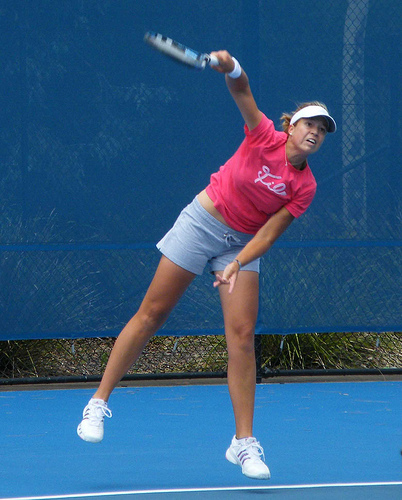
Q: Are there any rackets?
A: Yes, there is a racket.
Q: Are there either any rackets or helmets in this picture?
A: Yes, there is a racket.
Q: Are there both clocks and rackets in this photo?
A: No, there is a racket but no clocks.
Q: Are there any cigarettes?
A: No, there are no cigarettes.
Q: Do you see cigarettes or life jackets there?
A: No, there are no cigarettes or life jackets.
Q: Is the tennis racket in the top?
A: Yes, the tennis racket is in the top of the image.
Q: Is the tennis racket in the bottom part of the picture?
A: No, the tennis racket is in the top of the image.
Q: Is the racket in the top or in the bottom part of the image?
A: The racket is in the top of the image.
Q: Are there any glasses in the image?
A: No, there are no glasses.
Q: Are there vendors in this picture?
A: No, there are no vendors.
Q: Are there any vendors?
A: No, there are no vendors.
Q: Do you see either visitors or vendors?
A: No, there are no vendors or visitors.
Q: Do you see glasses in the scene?
A: No, there are no glasses.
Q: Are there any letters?
A: Yes, there are letters.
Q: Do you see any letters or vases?
A: Yes, there are letters.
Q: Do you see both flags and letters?
A: No, there are letters but no flags.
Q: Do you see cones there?
A: No, there are no cones.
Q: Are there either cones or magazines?
A: No, there are no cones or magazines.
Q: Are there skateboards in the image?
A: No, there are no skateboards.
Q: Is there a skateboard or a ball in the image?
A: No, there are no skateboards or balls.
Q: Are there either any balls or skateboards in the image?
A: No, there are no skateboards or balls.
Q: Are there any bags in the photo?
A: No, there are no bags.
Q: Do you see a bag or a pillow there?
A: No, there are no bags or pillows.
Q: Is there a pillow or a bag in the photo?
A: No, there are no bags or pillows.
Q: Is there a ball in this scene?
A: No, there are no balls.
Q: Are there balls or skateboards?
A: No, there are no balls or skateboards.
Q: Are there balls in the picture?
A: No, there are no balls.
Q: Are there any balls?
A: No, there are no balls.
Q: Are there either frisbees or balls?
A: No, there are no balls or frisbees.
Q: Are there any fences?
A: Yes, there is a fence.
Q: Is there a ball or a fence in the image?
A: Yes, there is a fence.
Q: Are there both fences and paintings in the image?
A: No, there is a fence but no paintings.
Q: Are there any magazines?
A: No, there are no magazines.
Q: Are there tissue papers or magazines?
A: No, there are no magazines or tissue papers.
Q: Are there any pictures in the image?
A: No, there are no pictures.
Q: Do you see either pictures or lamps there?
A: No, there are no pictures or lamps.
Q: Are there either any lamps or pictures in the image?
A: No, there are no pictures or lamps.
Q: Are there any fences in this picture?
A: Yes, there is a fence.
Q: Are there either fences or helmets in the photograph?
A: Yes, there is a fence.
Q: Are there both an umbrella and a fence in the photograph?
A: No, there is a fence but no umbrellas.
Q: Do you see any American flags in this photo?
A: No, there are no American flags.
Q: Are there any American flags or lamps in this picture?
A: No, there are no American flags or lamps.